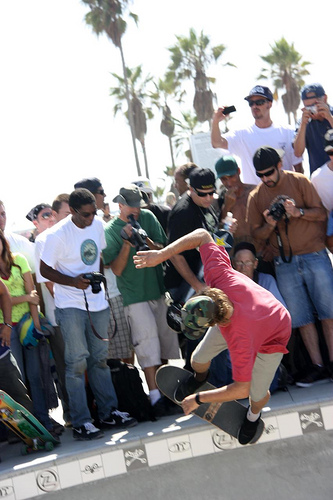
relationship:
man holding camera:
[244, 147, 331, 372] [267, 195, 288, 220]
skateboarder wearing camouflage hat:
[131, 227, 292, 447] [179, 295, 215, 341]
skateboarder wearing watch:
[131, 227, 292, 447] [189, 387, 207, 408]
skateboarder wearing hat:
[131, 227, 292, 447] [112, 184, 149, 209]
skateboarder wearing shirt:
[112, 210, 296, 452] [197, 232, 296, 387]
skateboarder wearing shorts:
[112, 210, 296, 452] [184, 318, 286, 406]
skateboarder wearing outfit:
[112, 210, 296, 452] [188, 243, 302, 407]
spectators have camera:
[28, 143, 333, 314] [120, 213, 150, 252]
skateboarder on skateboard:
[131, 227, 292, 447] [154, 361, 270, 457]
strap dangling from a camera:
[81, 278, 118, 342] [82, 271, 104, 294]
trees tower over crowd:
[81, 0, 315, 186] [0, 85, 332, 450]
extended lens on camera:
[91, 279, 101, 296] [79, 269, 107, 297]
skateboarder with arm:
[131, 227, 292, 447] [127, 224, 232, 269]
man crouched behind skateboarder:
[236, 242, 267, 281] [131, 227, 292, 447]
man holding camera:
[285, 80, 333, 184] [303, 104, 318, 118]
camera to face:
[303, 104, 318, 118] [296, 88, 332, 117]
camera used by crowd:
[267, 192, 296, 220] [0, 85, 332, 450]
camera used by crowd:
[118, 214, 151, 251] [0, 85, 332, 450]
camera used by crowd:
[82, 270, 103, 292] [0, 85, 332, 450]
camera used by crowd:
[220, 104, 235, 114] [0, 85, 332, 450]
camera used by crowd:
[303, 104, 319, 120] [0, 85, 332, 450]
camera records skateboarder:
[267, 192, 296, 220] [131, 227, 292, 447]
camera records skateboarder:
[118, 214, 151, 251] [131, 227, 292, 447]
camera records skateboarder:
[82, 270, 103, 292] [131, 227, 292, 447]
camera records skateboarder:
[220, 104, 235, 114] [131, 227, 292, 447]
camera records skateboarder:
[303, 104, 319, 120] [131, 227, 292, 447]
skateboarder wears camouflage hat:
[131, 227, 292, 447] [174, 293, 217, 341]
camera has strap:
[83, 271, 104, 293] [81, 278, 118, 342]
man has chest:
[240, 144, 332, 375] [258, 179, 325, 250]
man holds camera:
[240, 144, 332, 375] [266, 195, 296, 228]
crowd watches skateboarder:
[0, 85, 332, 450] [131, 227, 292, 447]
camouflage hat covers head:
[179, 295, 215, 341] [191, 289, 229, 318]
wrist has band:
[185, 384, 220, 410] [191, 386, 202, 402]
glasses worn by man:
[235, 258, 253, 267] [232, 249, 285, 308]